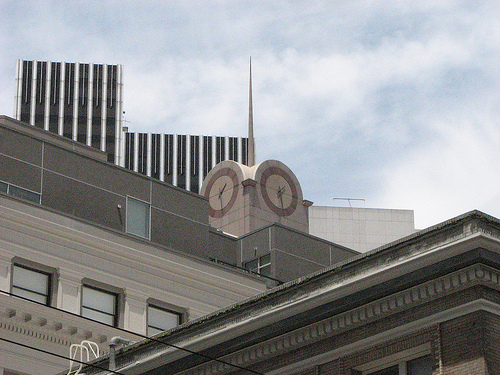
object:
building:
[1, 111, 371, 364]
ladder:
[61, 338, 103, 375]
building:
[61, 209, 499, 375]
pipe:
[106, 336, 135, 375]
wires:
[0, 290, 265, 375]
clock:
[204, 167, 239, 218]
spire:
[244, 55, 257, 161]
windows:
[7, 262, 50, 305]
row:
[7, 259, 183, 344]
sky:
[0, 0, 500, 230]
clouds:
[277, 31, 385, 94]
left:
[208, 184, 216, 209]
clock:
[261, 166, 298, 216]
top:
[21, 53, 134, 86]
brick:
[454, 326, 471, 347]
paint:
[49, 227, 106, 250]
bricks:
[256, 237, 264, 244]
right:
[285, 185, 295, 208]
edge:
[162, 181, 200, 195]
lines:
[72, 63, 79, 141]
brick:
[187, 205, 197, 212]